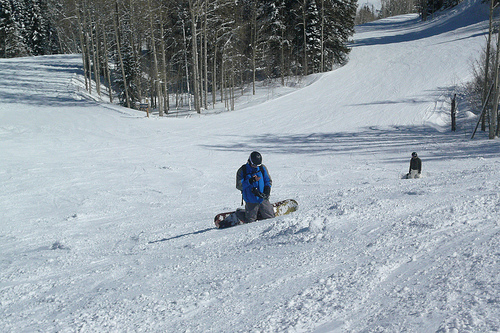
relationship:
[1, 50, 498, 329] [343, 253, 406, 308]
snow field covered with snow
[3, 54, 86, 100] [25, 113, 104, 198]
shadows cast on snow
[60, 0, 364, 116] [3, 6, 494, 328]
trees on snow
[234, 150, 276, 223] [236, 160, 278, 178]
man wears goggles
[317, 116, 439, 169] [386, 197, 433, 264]
shadows cast on snow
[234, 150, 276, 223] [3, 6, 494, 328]
man sitting down in snow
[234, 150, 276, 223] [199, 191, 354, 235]
man jkneeling down on snowboard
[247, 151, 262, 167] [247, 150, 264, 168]
helmet on head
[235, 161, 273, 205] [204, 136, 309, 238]
blue jacket on body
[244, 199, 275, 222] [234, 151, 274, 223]
pants on  a body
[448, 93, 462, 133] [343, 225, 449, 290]
tree stump in snow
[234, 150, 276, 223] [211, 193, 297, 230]
man on a snowboard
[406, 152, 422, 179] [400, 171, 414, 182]
boy on a snowboard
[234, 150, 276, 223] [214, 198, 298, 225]
man on a snowboard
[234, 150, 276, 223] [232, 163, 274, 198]
man wearing a blue jacket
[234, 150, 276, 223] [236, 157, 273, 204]
man wearing blue jacket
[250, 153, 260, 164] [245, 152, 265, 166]
helmet on head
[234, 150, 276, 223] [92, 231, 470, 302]
man kneeling on snow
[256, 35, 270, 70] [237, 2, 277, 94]
snow covered tree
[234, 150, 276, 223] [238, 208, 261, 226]
man on hi knee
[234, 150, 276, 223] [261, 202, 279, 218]
man on hi knee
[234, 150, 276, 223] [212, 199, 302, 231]
man hooked to board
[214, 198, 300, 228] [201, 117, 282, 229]
board on person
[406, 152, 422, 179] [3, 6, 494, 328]
boy kneeling on snow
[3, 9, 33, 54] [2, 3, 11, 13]
tree has snow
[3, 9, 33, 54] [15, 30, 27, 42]
tree has snow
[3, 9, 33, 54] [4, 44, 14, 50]
tree has snow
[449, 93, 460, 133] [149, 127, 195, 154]
tree stump of tree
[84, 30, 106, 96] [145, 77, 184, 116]
trunk of tree